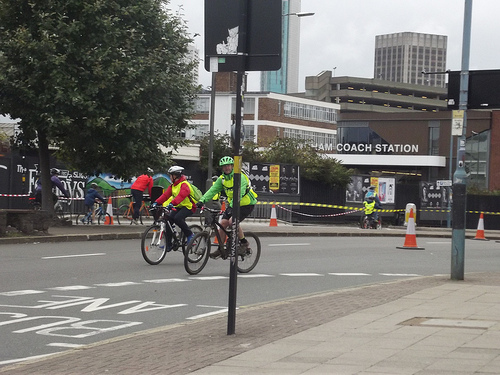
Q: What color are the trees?
A: Green.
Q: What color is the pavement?
A: Gray.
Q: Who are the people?
A: Bikers.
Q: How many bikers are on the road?
A: Two.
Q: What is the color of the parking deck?
A: Gray.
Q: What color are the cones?
A: Orange.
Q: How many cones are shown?
A: Five.